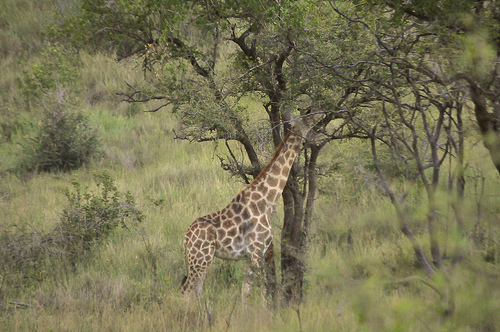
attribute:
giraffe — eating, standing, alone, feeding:
[180, 102, 333, 316]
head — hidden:
[297, 98, 330, 126]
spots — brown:
[182, 129, 300, 300]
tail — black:
[178, 238, 190, 291]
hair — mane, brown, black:
[244, 126, 295, 186]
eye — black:
[304, 106, 314, 115]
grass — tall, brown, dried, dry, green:
[3, 9, 489, 329]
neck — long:
[254, 124, 306, 205]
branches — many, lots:
[76, 1, 406, 179]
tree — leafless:
[267, 6, 470, 274]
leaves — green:
[63, 3, 392, 193]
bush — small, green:
[22, 1, 499, 303]